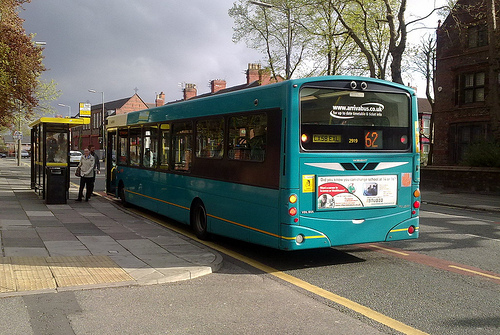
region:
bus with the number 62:
[351, 115, 389, 170]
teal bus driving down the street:
[275, 70, 330, 257]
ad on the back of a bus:
[305, 163, 417, 230]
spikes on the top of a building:
[173, 71, 205, 98]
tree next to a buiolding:
[343, 12, 403, 62]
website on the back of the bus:
[318, 91, 399, 126]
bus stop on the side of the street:
[16, 97, 124, 243]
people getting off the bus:
[62, 126, 114, 206]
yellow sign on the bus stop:
[72, 100, 95, 120]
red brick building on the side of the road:
[438, 12, 498, 155]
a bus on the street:
[104, 76, 467, 261]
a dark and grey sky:
[4, 0, 223, 108]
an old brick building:
[421, 4, 497, 192]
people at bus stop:
[35, 102, 165, 232]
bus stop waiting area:
[23, 107, 138, 209]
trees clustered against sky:
[203, 1, 440, 84]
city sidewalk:
[4, 71, 111, 333]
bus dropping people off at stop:
[45, 32, 472, 310]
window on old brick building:
[440, 62, 499, 112]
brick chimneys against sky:
[157, 49, 289, 96]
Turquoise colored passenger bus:
[103, 72, 420, 252]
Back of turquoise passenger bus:
[290, 75, 420, 245]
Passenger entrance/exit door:
[105, 123, 135, 203]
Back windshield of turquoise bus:
[296, 83, 413, 154]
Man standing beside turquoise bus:
[75, 141, 100, 203]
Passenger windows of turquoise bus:
[102, 103, 282, 184]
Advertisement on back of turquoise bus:
[315, 171, 395, 209]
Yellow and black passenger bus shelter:
[25, 110, 90, 200]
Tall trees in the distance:
[225, 0, 405, 81]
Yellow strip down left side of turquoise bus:
[137, 185, 334, 246]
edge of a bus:
[291, 92, 301, 125]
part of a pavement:
[154, 234, 167, 284]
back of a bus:
[351, 217, 368, 222]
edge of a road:
[438, 187, 453, 202]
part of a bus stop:
[53, 173, 63, 206]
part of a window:
[214, 140, 225, 152]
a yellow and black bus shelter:
[25, 110, 90, 204]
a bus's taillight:
[289, 194, 298, 203]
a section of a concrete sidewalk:
[77, 233, 117, 243]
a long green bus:
[98, 76, 426, 248]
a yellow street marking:
[451, 262, 498, 280]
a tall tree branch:
[308, 5, 377, 75]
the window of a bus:
[194, 121, 227, 160]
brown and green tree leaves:
[0, 0, 56, 147]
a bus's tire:
[188, 203, 210, 238]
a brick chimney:
[210, 77, 227, 91]